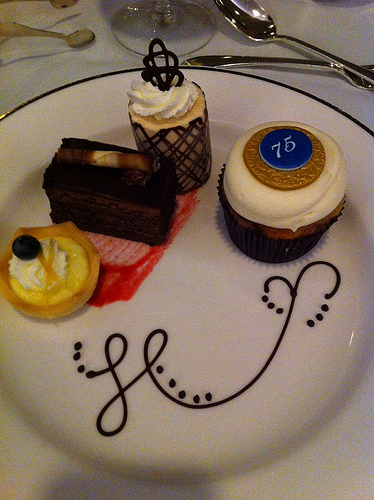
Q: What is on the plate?
A: Pastries.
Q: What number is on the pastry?
A: 75.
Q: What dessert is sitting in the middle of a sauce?
A: Chocolate cake.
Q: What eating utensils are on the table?
A: Spoon and fork.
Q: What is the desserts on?
A: A plate.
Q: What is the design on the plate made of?
A: Chocolate.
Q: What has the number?
A: A cupcake.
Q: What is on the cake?
A: Frosting.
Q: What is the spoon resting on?
A: The fork.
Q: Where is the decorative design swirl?
A: On the plate.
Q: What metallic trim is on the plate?
A: Gold.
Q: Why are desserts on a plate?
A: To be eaten.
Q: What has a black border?
A: The plate.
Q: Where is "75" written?
A: On cupcake.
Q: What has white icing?
A: Cupcake on right.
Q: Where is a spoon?
A: Next to the plate.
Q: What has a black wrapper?
A: The cupcake.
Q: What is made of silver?
A: The utensils.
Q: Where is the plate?
A: On table.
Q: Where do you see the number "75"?
A: On the cupcake.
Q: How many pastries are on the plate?
A: 4.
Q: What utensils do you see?
A: Spoon and knife.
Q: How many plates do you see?
A: 1.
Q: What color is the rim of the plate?
A: Gold.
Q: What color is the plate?
A: White.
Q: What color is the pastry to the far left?
A: Yellow.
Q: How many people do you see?
A: 0.